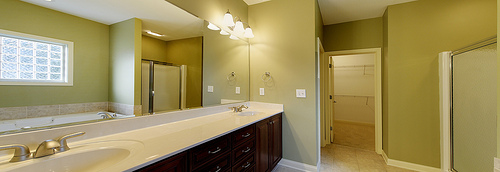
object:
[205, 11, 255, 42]
lights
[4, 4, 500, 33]
ceiling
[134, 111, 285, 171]
cabinets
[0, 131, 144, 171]
sink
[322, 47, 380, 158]
door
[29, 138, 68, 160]
faucet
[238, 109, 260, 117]
sink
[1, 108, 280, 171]
counter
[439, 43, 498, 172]
shower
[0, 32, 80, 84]
window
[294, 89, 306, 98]
switch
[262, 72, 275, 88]
rack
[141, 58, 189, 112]
shower door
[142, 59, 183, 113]
mirror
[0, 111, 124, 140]
bathtub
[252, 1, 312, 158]
wall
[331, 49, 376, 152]
closet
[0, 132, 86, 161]
handles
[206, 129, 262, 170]
drawers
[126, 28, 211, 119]
wall